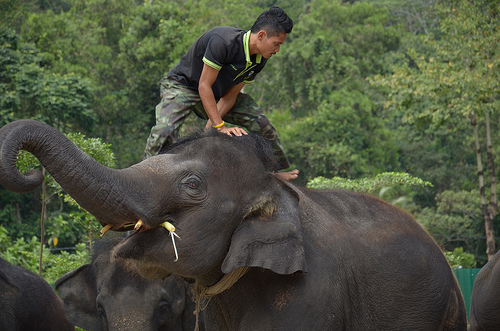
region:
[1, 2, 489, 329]
A man is on an elephant.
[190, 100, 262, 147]
The man's hand is on the elephant.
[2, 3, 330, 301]
The man is on the elephant's head.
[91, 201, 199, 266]
The elephant is eating.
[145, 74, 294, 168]
The man wears camouflage pants.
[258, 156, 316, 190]
The man is barefoot.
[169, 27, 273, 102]
The man's shirt is blue and green.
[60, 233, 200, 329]
A second elephant is behind the first.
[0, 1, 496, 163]
Trees are behind the elephants.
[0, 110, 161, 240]
The elephant's trunk is in the air.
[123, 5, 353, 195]
The man climbs over an elephant.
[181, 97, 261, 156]
The man's hands are on the elephant.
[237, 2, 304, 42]
The man has dark hair.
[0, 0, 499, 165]
Trees are behind the elephant.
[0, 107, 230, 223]
The elephant's trunk is raised.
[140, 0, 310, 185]
A man on top of an elephant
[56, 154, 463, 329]
The elephant is grey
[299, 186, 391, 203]
The elephant has very short fur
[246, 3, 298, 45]
The man has an interesting haircut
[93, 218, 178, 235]
The elephant has short tusks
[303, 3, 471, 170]
Green trees in the background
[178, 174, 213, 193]
The elephant's eyes are open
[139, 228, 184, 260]
The elephant is eating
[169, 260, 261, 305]
Cloth around elephant's neck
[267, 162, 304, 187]
The man is barefoot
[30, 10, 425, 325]
a man on an elephant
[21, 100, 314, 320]
an elephant with something in its mouth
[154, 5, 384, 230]
a man wearing a black and yellow shirt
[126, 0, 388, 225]
a man with spike hair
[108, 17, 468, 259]
a man with black hair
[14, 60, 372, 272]
an elephant with large trunk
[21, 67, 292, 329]
elephants trunk in the air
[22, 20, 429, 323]
an elephant standing up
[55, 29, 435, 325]
an elephant that is outside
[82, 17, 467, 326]
a man on a large elephant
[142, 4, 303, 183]
The man on the elephant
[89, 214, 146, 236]
The nearest elephant's tusks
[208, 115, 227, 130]
The man's yellow wristband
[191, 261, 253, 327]
The rope collar on the nearest elephant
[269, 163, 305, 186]
The man's exposed foot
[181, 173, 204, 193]
The left eye of the elephant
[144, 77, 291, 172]
The man's camo pants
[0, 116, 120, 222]
The trunk of the nearest elephant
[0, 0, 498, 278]
The trees behind the elephants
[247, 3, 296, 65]
The head of the man